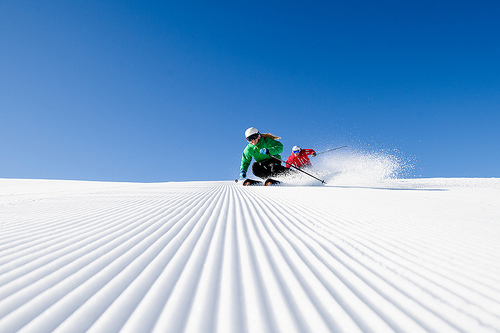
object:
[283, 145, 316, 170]
man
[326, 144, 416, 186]
dust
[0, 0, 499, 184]
sky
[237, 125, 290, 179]
people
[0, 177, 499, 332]
mountain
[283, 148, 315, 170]
jacket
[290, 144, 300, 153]
helmet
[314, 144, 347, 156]
ski poles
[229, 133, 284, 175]
jacket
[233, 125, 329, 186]
skiing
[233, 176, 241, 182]
skipole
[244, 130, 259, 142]
glasses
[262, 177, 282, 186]
skis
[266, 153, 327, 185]
ski pole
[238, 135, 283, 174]
green coat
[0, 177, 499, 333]
snow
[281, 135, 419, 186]
snow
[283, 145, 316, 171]
person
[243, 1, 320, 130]
part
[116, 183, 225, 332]
lines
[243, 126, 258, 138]
helmet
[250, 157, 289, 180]
pants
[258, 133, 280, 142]
hair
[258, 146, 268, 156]
hand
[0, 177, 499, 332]
ground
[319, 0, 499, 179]
part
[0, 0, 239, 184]
part